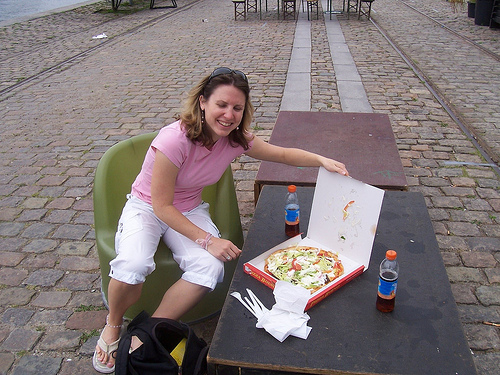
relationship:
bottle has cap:
[371, 248, 403, 315] [384, 245, 398, 264]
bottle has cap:
[279, 178, 304, 235] [281, 182, 298, 196]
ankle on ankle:
[105, 312, 124, 336] [91, 312, 124, 338]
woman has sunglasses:
[75, 59, 339, 362] [209, 59, 258, 92]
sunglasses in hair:
[209, 59, 258, 92] [175, 61, 260, 150]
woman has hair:
[75, 59, 339, 362] [175, 61, 260, 150]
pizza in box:
[265, 246, 341, 291] [253, 160, 389, 302]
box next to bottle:
[253, 160, 389, 302] [371, 248, 403, 315]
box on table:
[253, 160, 389, 302] [205, 181, 479, 365]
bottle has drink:
[371, 248, 403, 315] [376, 272, 398, 308]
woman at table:
[75, 59, 339, 362] [205, 181, 479, 365]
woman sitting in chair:
[75, 59, 339, 362] [83, 124, 243, 322]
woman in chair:
[75, 59, 339, 362] [83, 124, 243, 322]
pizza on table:
[265, 246, 341, 291] [205, 181, 479, 365]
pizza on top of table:
[265, 246, 341, 291] [205, 181, 479, 365]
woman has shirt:
[75, 59, 339, 362] [133, 126, 254, 212]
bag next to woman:
[121, 312, 204, 368] [75, 59, 339, 362]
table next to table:
[205, 181, 479, 365] [251, 108, 405, 183]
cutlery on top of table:
[228, 283, 272, 326] [205, 181, 479, 365]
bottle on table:
[371, 248, 403, 315] [205, 181, 479, 365]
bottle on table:
[279, 178, 304, 235] [205, 181, 479, 365]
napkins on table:
[261, 277, 318, 350] [205, 181, 479, 365]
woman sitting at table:
[75, 59, 339, 362] [205, 181, 479, 365]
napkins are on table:
[261, 277, 318, 350] [205, 181, 479, 365]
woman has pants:
[75, 59, 339, 362] [111, 198, 225, 285]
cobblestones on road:
[38, 124, 85, 154] [2, 23, 100, 348]